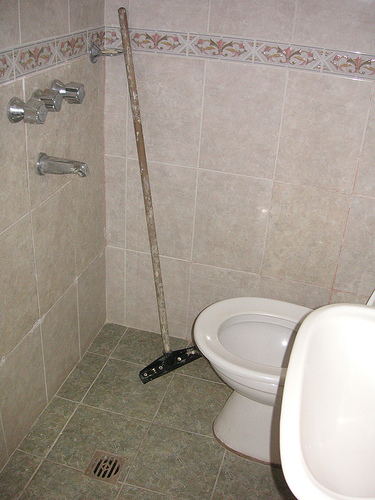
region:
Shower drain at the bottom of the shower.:
[84, 443, 131, 491]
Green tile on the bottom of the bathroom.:
[141, 423, 221, 497]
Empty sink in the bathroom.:
[293, 351, 373, 497]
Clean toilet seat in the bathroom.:
[204, 305, 275, 374]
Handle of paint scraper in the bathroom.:
[113, 5, 170, 292]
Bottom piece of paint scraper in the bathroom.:
[131, 362, 199, 379]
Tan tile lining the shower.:
[35, 305, 84, 371]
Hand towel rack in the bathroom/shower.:
[91, 35, 121, 65]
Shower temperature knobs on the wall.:
[8, 84, 99, 123]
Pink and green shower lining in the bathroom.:
[161, 30, 292, 71]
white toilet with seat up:
[189, 283, 373, 467]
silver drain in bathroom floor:
[82, 440, 126, 485]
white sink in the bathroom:
[274, 309, 374, 499]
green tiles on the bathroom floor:
[6, 315, 301, 498]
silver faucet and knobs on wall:
[15, 77, 102, 185]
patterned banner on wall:
[0, 21, 374, 85]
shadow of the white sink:
[248, 301, 312, 499]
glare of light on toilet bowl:
[203, 329, 290, 352]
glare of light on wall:
[257, 197, 276, 218]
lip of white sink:
[266, 296, 368, 498]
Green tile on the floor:
[0, 320, 299, 499]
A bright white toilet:
[188, 287, 373, 468]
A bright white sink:
[275, 301, 371, 498]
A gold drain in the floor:
[81, 446, 126, 484]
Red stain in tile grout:
[321, 150, 370, 305]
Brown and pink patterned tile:
[0, 23, 374, 90]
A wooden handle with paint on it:
[116, 6, 173, 354]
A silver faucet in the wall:
[33, 150, 92, 180]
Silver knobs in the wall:
[6, 78, 86, 124]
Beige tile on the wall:
[0, 0, 374, 474]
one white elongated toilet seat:
[191, 289, 285, 407]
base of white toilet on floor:
[204, 396, 276, 471]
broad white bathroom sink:
[276, 289, 374, 498]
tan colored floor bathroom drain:
[79, 446, 131, 486]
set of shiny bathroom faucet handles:
[6, 77, 90, 128]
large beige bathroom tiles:
[160, 63, 350, 290]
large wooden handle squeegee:
[105, 5, 199, 384]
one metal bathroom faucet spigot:
[33, 149, 93, 182]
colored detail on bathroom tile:
[137, 17, 372, 80]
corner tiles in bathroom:
[80, 237, 141, 363]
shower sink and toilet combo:
[5, 8, 372, 496]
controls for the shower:
[9, 58, 90, 126]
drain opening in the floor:
[79, 452, 134, 483]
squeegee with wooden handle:
[109, 9, 212, 393]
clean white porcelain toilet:
[193, 278, 318, 471]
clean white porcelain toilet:
[270, 286, 371, 497]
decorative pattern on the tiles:
[6, 30, 371, 86]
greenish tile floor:
[1, 312, 309, 495]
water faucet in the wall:
[30, 156, 103, 186]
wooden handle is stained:
[114, 7, 179, 357]